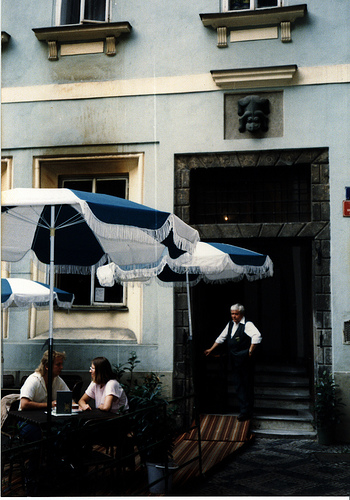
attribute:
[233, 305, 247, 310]
hair — gray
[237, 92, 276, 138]
statue — small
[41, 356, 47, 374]
hair — blonde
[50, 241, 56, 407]
pole — metal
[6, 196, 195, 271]
umbrella — blue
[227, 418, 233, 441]
stripe — brown